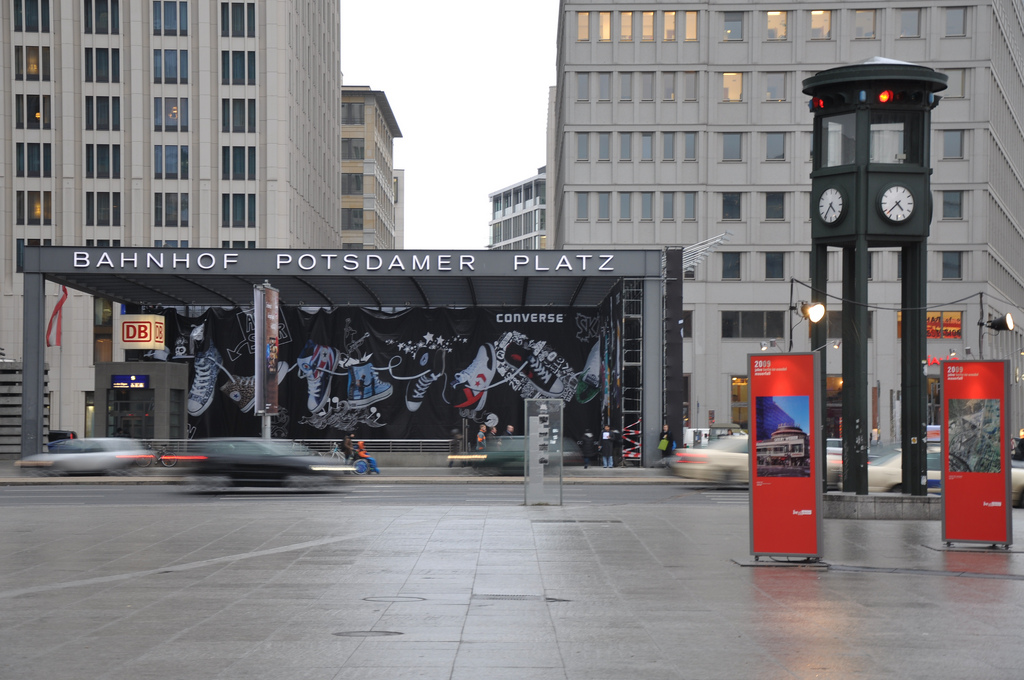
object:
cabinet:
[221, 51, 256, 86]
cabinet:
[723, 312, 784, 340]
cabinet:
[723, 252, 740, 278]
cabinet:
[766, 252, 783, 278]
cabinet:
[944, 252, 961, 278]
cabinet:
[944, 191, 961, 218]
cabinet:
[942, 129, 964, 159]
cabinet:
[936, 68, 964, 99]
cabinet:
[945, 5, 967, 36]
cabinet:
[893, 10, 921, 37]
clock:
[881, 185, 917, 222]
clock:
[818, 187, 845, 225]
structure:
[16, 244, 684, 460]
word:
[69, 247, 617, 275]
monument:
[800, 55, 943, 498]